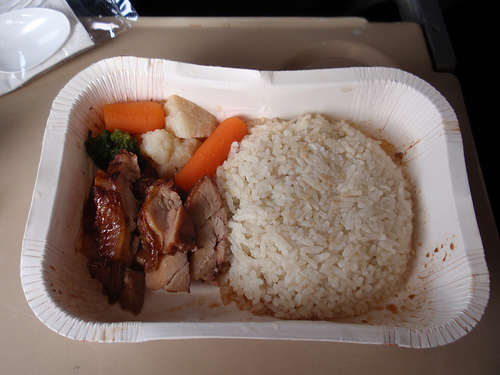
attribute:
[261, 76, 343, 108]
tray — white, beige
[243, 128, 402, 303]
rice — white, cooked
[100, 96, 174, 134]
carrot — orange, small, cooked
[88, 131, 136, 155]
broccoli — green, chopped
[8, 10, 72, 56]
spoon — white, plastic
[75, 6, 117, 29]
wrapper — plastic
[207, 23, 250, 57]
table — beige, tan, silver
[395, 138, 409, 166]
sauce — brown, meat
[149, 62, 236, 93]
container — white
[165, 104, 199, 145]
cauliflower — cooked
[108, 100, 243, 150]
carrots — cooked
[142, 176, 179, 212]
pork — kalua